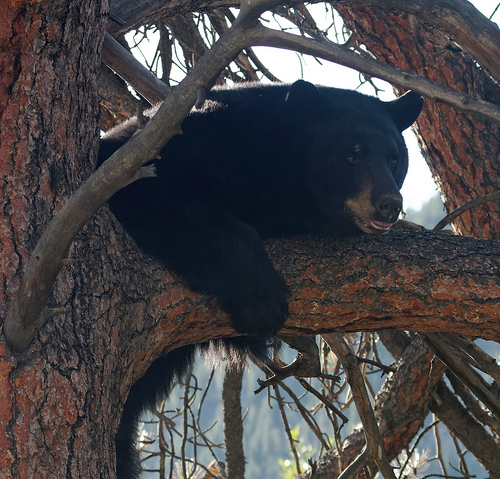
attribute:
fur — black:
[216, 128, 245, 146]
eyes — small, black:
[337, 147, 406, 175]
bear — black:
[81, 29, 458, 397]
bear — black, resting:
[98, 79, 423, 338]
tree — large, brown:
[1, 0, 149, 473]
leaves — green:
[279, 420, 307, 463]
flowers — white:
[235, 414, 340, 477]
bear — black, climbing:
[124, 73, 438, 326]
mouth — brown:
[349, 187, 399, 234]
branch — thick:
[101, 199, 498, 407]